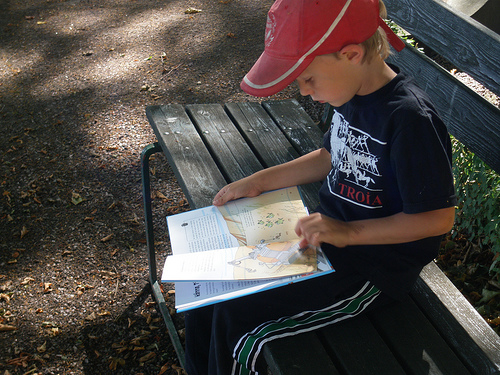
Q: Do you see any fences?
A: No, there are no fences.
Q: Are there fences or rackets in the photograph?
A: No, there are no fences or rackets.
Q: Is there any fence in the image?
A: No, there are no fences.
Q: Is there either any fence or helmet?
A: No, there are no fences or helmets.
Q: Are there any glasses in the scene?
A: No, there are no glasses.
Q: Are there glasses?
A: No, there are no glasses.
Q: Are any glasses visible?
A: No, there are no glasses.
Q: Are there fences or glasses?
A: No, there are no glasses or fences.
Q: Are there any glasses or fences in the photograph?
A: No, there are no glasses or fences.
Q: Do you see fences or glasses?
A: No, there are no glasses or fences.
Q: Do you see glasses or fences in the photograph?
A: No, there are no glasses or fences.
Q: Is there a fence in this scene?
A: No, there are no fences.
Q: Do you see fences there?
A: No, there are no fences.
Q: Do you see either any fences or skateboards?
A: No, there are no fences or skateboards.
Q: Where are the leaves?
A: The leaves are on the ground.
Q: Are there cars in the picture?
A: No, there are no cars.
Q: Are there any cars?
A: No, there are no cars.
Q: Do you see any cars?
A: No, there are no cars.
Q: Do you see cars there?
A: No, there are no cars.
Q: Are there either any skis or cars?
A: No, there are no cars or skis.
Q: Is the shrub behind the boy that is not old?
A: Yes, the shrub is behind the boy.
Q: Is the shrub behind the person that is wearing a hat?
A: Yes, the shrub is behind the boy.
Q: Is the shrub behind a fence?
A: No, the shrub is behind the boy.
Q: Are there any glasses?
A: No, there are no glasses.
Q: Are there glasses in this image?
A: No, there are no glasses.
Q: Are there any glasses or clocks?
A: No, there are no glasses or clocks.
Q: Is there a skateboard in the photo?
A: No, there are no skateboards.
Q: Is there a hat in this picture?
A: Yes, there is a hat.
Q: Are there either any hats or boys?
A: Yes, there is a hat.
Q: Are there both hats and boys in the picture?
A: Yes, there are both a hat and a boy.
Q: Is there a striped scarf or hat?
A: Yes, there is a striped hat.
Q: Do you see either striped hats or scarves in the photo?
A: Yes, there is a striped hat.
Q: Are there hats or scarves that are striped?
A: Yes, the hat is striped.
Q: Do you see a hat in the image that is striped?
A: Yes, there is a striped hat.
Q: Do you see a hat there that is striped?
A: Yes, there is a hat that is striped.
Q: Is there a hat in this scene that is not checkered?
A: Yes, there is a striped hat.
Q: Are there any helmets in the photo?
A: No, there are no helmets.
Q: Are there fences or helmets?
A: No, there are no helmets or fences.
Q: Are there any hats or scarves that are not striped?
A: No, there is a hat but it is striped.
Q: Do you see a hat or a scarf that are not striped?
A: No, there is a hat but it is striped.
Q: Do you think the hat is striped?
A: Yes, the hat is striped.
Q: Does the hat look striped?
A: Yes, the hat is striped.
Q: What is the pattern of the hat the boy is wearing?
A: The hat is striped.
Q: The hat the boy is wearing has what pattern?
A: The hat is striped.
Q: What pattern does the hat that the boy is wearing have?
A: The hat has striped pattern.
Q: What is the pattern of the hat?
A: The hat is striped.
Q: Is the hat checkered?
A: No, the hat is striped.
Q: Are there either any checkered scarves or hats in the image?
A: No, there is a hat but it is striped.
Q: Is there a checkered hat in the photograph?
A: No, there is a hat but it is striped.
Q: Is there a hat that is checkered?
A: No, there is a hat but it is striped.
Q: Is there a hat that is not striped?
A: No, there is a hat but it is striped.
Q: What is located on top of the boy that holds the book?
A: The hat is on top of the boy.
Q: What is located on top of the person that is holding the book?
A: The hat is on top of the boy.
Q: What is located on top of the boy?
A: The hat is on top of the boy.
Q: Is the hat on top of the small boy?
A: Yes, the hat is on top of the boy.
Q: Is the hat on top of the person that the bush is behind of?
A: Yes, the hat is on top of the boy.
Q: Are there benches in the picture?
A: Yes, there is a bench.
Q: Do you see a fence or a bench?
A: Yes, there is a bench.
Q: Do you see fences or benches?
A: Yes, there is a bench.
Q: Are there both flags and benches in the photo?
A: No, there is a bench but no flags.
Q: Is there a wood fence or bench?
A: Yes, there is a wood bench.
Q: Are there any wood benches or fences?
A: Yes, there is a wood bench.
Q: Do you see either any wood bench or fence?
A: Yes, there is a wood bench.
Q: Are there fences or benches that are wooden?
A: Yes, the bench is wooden.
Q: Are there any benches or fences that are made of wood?
A: Yes, the bench is made of wood.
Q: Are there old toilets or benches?
A: Yes, there is an old bench.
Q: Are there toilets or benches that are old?
A: Yes, the bench is old.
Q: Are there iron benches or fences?
A: Yes, there is an iron bench.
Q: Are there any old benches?
A: Yes, there is an old bench.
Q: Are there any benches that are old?
A: Yes, there is a bench that is old.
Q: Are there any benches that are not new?
A: Yes, there is a old bench.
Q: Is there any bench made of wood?
A: Yes, there is a bench that is made of wood.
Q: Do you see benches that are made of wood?
A: Yes, there is a bench that is made of wood.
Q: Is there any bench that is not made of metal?
A: Yes, there is a bench that is made of wood.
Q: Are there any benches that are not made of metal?
A: Yes, there is a bench that is made of wood.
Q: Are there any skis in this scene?
A: No, there are no skis.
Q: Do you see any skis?
A: No, there are no skis.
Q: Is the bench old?
A: Yes, the bench is old.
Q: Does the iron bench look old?
A: Yes, the bench is old.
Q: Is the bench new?
A: No, the bench is old.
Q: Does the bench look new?
A: No, the bench is old.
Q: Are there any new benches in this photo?
A: No, there is a bench but it is old.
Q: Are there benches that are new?
A: No, there is a bench but it is old.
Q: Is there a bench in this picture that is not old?
A: No, there is a bench but it is old.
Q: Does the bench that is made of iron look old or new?
A: The bench is old.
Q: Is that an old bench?
A: Yes, that is an old bench.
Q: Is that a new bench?
A: No, that is an old bench.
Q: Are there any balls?
A: No, there are no balls.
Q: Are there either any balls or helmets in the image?
A: No, there are no balls or helmets.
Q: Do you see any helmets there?
A: No, there are no helmets.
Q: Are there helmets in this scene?
A: No, there are no helmets.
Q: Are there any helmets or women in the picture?
A: No, there are no helmets or women.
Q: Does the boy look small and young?
A: Yes, the boy is small and young.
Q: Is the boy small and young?
A: Yes, the boy is small and young.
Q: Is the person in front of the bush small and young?
A: Yes, the boy is small and young.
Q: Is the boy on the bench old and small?
A: No, the boy is small but young.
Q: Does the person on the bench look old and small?
A: No, the boy is small but young.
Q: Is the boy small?
A: Yes, the boy is small.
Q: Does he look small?
A: Yes, the boy is small.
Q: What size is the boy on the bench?
A: The boy is small.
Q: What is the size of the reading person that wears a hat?
A: The boy is small.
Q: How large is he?
A: The boy is small.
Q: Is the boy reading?
A: Yes, the boy is reading.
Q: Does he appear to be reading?
A: Yes, the boy is reading.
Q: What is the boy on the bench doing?
A: The boy is reading.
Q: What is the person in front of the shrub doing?
A: The boy is reading.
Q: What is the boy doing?
A: The boy is reading.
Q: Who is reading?
A: The boy is reading.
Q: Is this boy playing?
A: No, the boy is reading.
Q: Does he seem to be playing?
A: No, the boy is reading.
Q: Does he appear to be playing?
A: No, the boy is reading.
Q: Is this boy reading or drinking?
A: The boy is reading.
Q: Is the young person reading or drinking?
A: The boy is reading.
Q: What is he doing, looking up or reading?
A: The boy is reading.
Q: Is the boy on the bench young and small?
A: Yes, the boy is young and small.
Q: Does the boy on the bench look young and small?
A: Yes, the boy is young and small.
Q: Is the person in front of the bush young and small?
A: Yes, the boy is young and small.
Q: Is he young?
A: Yes, the boy is young.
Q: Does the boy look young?
A: Yes, the boy is young.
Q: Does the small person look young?
A: Yes, the boy is young.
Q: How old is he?
A: The boy is young.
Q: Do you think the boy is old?
A: No, the boy is young.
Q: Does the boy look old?
A: No, the boy is young.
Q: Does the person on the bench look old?
A: No, the boy is young.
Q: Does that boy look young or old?
A: The boy is young.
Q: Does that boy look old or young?
A: The boy is young.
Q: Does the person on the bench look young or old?
A: The boy is young.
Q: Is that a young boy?
A: Yes, that is a young boy.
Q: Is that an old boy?
A: No, that is a young boy.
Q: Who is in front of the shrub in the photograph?
A: The boy is in front of the shrub.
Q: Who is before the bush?
A: The boy is in front of the shrub.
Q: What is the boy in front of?
A: The boy is in front of the bush.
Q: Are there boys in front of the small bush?
A: Yes, there is a boy in front of the bush.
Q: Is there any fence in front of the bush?
A: No, there is a boy in front of the bush.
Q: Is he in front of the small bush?
A: Yes, the boy is in front of the bush.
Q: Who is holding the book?
A: The boy is holding the book.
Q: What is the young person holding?
A: The boy is holding the book.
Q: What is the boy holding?
A: The boy is holding the book.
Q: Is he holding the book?
A: Yes, the boy is holding the book.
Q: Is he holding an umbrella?
A: No, the boy is holding the book.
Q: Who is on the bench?
A: The boy is on the bench.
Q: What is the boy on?
A: The boy is on the bench.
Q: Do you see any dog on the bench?
A: No, there is a boy on the bench.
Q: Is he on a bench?
A: Yes, the boy is on a bench.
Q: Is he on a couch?
A: No, the boy is on a bench.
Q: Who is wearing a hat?
A: The boy is wearing a hat.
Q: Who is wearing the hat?
A: The boy is wearing a hat.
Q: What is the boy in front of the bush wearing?
A: The boy is wearing a hat.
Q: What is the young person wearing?
A: The boy is wearing a hat.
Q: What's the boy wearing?
A: The boy is wearing a hat.